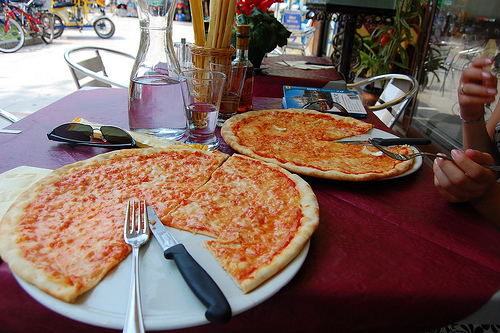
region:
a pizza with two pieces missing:
[5, 145, 319, 329]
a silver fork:
[122, 197, 154, 331]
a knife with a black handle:
[143, 203, 233, 323]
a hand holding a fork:
[363, 130, 492, 184]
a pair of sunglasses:
[45, 118, 137, 150]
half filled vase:
[128, 2, 191, 149]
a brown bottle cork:
[233, 19, 255, 52]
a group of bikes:
[1, 3, 118, 50]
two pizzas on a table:
[8, 105, 425, 326]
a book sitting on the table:
[281, 82, 368, 118]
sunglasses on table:
[33, 115, 157, 163]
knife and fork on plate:
[87, 186, 235, 331]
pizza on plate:
[0, 130, 329, 331]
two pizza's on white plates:
[13, 93, 438, 320]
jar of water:
[117, 0, 237, 157]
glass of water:
[182, 58, 259, 152]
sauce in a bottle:
[223, 17, 274, 114]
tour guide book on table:
[272, 82, 408, 116]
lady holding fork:
[344, 117, 499, 208]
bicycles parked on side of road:
[0, 0, 129, 64]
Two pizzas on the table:
[0, 104, 437, 309]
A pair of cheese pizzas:
[0, 95, 434, 310]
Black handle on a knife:
[161, 233, 236, 331]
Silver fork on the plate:
[121, 197, 153, 331]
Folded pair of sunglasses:
[40, 117, 138, 151]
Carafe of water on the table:
[122, 0, 194, 138]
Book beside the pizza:
[273, 82, 370, 122]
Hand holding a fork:
[363, 133, 498, 210]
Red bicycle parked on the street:
[0, 3, 60, 50]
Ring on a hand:
[457, 82, 467, 96]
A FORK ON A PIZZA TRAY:
[123, 195, 150, 330]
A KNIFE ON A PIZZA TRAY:
[142, 198, 239, 325]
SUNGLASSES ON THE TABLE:
[43, 117, 150, 149]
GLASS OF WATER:
[176, 62, 230, 147]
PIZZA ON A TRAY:
[0, 141, 325, 331]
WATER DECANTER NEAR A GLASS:
[125, 22, 192, 144]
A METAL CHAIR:
[61, 35, 164, 87]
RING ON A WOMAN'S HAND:
[453, 79, 468, 97]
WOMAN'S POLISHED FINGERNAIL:
[475, 62, 499, 86]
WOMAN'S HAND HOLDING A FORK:
[365, 129, 499, 229]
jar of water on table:
[120, 0, 233, 153]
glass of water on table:
[182, 64, 247, 136]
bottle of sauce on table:
[222, 16, 265, 109]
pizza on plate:
[0, 137, 351, 327]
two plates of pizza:
[10, 87, 498, 324]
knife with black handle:
[138, 195, 257, 332]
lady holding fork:
[371, 125, 498, 196]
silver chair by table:
[334, 65, 434, 128]